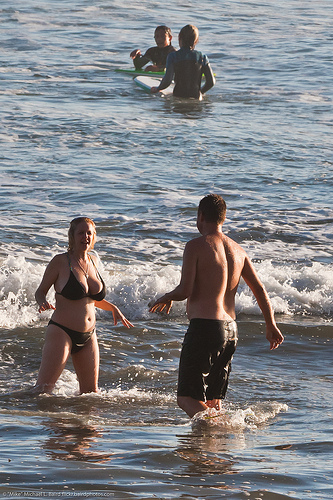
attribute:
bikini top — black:
[56, 252, 107, 299]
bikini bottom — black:
[47, 320, 97, 353]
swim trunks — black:
[176, 318, 238, 397]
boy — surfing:
[152, 24, 215, 99]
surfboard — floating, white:
[134, 75, 175, 96]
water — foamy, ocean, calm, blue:
[2, 1, 332, 498]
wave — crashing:
[5, 249, 332, 328]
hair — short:
[197, 195, 226, 222]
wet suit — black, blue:
[161, 47, 216, 95]